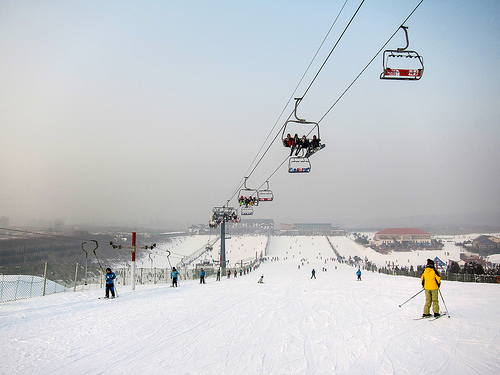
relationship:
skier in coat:
[104, 267, 120, 294] [107, 273, 115, 288]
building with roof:
[374, 227, 432, 240] [373, 227, 434, 234]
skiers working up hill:
[94, 263, 274, 294] [269, 229, 360, 290]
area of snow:
[276, 302, 366, 368] [239, 300, 387, 370]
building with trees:
[374, 221, 437, 244] [351, 232, 437, 259]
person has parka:
[420, 258, 442, 317] [417, 262, 444, 293]